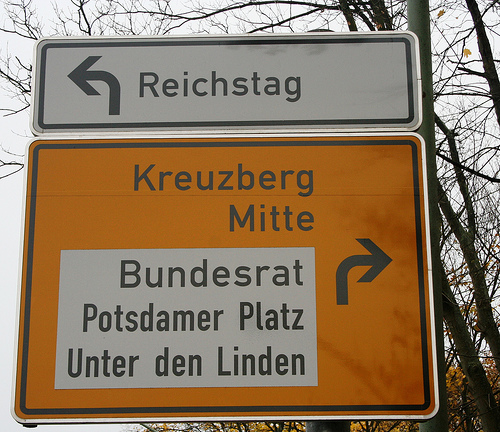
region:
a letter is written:
[120, 255, 143, 295]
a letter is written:
[144, 261, 163, 291]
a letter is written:
[166, 260, 186, 293]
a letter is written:
[184, 247, 213, 294]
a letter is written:
[209, 260, 234, 288]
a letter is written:
[231, 260, 256, 294]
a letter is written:
[251, 256, 274, 288]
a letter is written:
[267, 260, 289, 292]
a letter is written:
[288, 255, 312, 290]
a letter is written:
[78, 298, 106, 337]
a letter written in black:
[114, 251, 142, 293]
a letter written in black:
[142, 260, 167, 287]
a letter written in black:
[165, 259, 187, 289]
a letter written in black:
[189, 252, 216, 297]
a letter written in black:
[209, 257, 235, 290]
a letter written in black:
[226, 253, 253, 293]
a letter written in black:
[253, 257, 274, 291]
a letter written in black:
[269, 257, 291, 294]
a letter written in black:
[289, 255, 313, 306]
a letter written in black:
[209, 323, 234, 382]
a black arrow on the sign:
[59, 48, 135, 121]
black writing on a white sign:
[133, 62, 310, 104]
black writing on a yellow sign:
[125, 153, 321, 241]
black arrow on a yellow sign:
[328, 227, 396, 313]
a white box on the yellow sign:
[46, 242, 324, 397]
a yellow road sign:
[7, 127, 468, 429]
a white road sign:
[27, 30, 432, 133]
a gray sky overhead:
[0, 0, 498, 430]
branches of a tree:
[0, 0, 47, 47]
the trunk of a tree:
[427, 254, 496, 429]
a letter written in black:
[62, 340, 84, 377]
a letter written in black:
[81, 349, 104, 380]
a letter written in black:
[98, 347, 115, 380]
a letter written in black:
[108, 350, 125, 377]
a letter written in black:
[123, 343, 145, 378]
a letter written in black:
[151, 343, 173, 380]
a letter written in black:
[169, 348, 190, 380]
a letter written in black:
[186, 351, 203, 380]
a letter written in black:
[215, 341, 233, 381]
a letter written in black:
[229, 344, 243, 379]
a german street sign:
[13, 6, 487, 430]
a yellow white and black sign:
[18, 130, 429, 426]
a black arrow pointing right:
[324, 231, 397, 307]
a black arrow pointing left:
[58, 52, 128, 118]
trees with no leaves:
[397, 4, 491, 430]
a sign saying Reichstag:
[129, 52, 312, 109]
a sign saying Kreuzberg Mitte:
[109, 152, 333, 234]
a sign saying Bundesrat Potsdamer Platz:
[49, 251, 313, 391]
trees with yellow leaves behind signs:
[287, 351, 491, 429]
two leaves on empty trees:
[425, 2, 481, 68]